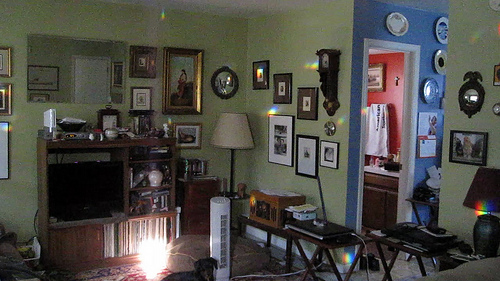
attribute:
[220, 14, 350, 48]
wall — green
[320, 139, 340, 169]
picture — hanging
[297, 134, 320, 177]
picture — hanging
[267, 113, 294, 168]
picture — hanging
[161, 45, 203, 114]
picture — gold, hanging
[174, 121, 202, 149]
picture — hanging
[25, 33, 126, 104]
mirror — large, glass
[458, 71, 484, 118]
mirror — glass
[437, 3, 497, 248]
wall — green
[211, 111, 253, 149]
lampshade — tan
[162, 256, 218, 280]
dog — black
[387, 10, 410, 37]
plate — hanging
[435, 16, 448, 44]
plate — hanging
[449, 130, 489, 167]
picture — hanging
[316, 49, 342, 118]
clock — brown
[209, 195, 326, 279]
fan — white, portable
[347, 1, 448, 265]
wall — blue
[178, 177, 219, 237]
shelf — for books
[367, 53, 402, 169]
wall — red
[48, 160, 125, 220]
tv — sectioned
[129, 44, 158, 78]
picture — hanging